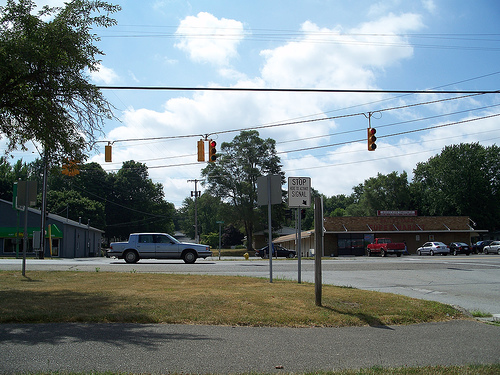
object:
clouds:
[80, 0, 500, 210]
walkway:
[0, 318, 500, 375]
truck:
[366, 238, 406, 258]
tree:
[0, 0, 126, 183]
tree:
[410, 141, 500, 241]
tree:
[352, 170, 411, 217]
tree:
[325, 193, 377, 217]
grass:
[0, 266, 493, 326]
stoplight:
[367, 127, 377, 151]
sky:
[0, 0, 500, 213]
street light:
[366, 127, 377, 151]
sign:
[287, 176, 311, 208]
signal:
[105, 127, 377, 163]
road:
[0, 234, 499, 326]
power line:
[92, 23, 499, 51]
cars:
[254, 245, 296, 259]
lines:
[0, 23, 500, 171]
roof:
[322, 215, 470, 231]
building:
[271, 210, 489, 258]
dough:
[76, 152, 169, 222]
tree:
[104, 159, 165, 239]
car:
[107, 232, 213, 263]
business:
[323, 209, 489, 257]